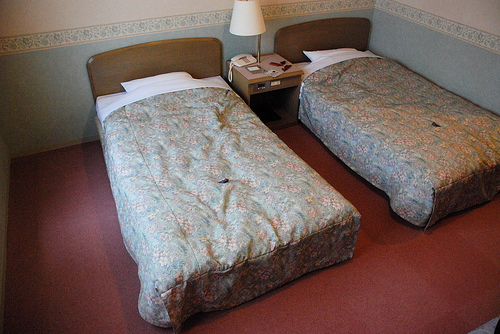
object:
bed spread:
[96, 78, 361, 330]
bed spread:
[296, 50, 500, 230]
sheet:
[297, 56, 497, 227]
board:
[272, 17, 372, 63]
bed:
[87, 37, 361, 331]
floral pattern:
[303, 193, 313, 203]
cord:
[228, 62, 235, 83]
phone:
[227, 53, 257, 82]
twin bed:
[84, 17, 499, 333]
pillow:
[120, 71, 193, 93]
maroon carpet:
[3, 121, 500, 334]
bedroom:
[0, 0, 499, 334]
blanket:
[96, 80, 362, 328]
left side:
[0, 59, 96, 333]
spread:
[251, 233, 308, 268]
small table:
[227, 52, 305, 129]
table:
[228, 52, 303, 134]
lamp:
[230, 0, 267, 63]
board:
[86, 36, 224, 101]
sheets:
[95, 101, 375, 298]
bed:
[273, 17, 500, 230]